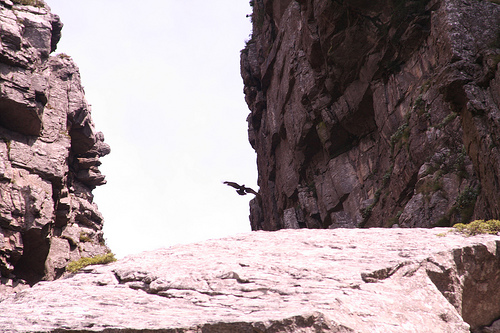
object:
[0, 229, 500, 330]
rock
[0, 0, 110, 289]
rock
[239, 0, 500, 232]
rock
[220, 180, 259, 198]
bird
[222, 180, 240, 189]
wing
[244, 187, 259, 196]
wing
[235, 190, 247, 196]
tail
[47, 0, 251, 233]
sky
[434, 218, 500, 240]
grass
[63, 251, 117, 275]
grass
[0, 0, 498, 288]
rocks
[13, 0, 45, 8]
plant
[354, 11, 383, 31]
crack